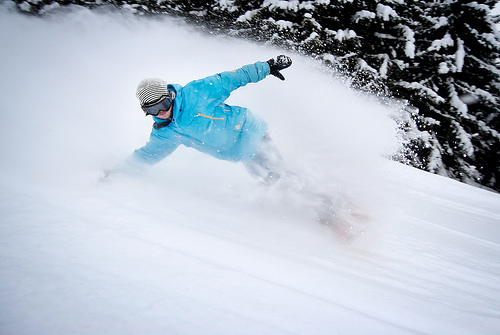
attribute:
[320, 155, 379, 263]
snowboard — red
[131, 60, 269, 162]
coat — blue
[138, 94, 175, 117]
goggles — snow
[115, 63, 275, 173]
coat — blue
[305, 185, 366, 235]
ski boots — white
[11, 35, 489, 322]
snow — large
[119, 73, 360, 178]
coat — blue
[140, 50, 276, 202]
jacket — blue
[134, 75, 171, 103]
hat — white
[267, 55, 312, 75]
glove — black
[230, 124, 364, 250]
ski pants — white 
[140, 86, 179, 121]
goggles — white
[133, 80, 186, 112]
hat — Black , White 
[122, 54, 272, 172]
jacket — blue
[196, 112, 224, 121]
zipper — yellow